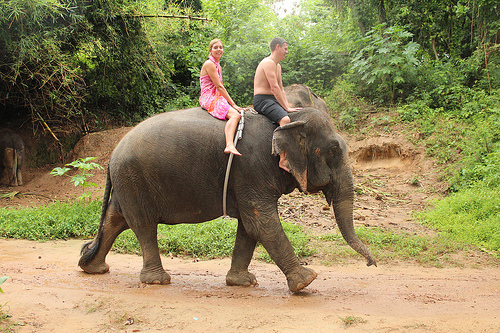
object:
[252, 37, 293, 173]
man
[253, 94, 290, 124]
shorts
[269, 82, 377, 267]
head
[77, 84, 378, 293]
elephant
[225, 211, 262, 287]
leg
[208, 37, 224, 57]
head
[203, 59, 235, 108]
arm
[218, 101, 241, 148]
leg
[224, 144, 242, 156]
foot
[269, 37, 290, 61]
head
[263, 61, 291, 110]
arm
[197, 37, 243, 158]
woman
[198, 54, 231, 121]
dress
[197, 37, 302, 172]
couple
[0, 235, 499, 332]
ground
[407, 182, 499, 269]
grass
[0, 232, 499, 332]
path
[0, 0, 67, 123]
trees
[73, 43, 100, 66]
leaves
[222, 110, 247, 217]
harness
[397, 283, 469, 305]
elephant tracks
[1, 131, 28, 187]
stump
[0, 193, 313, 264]
grass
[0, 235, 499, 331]
dirt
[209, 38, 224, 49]
hair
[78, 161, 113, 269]
tail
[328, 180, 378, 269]
trunk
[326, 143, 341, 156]
eye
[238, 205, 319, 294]
leg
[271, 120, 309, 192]
ear